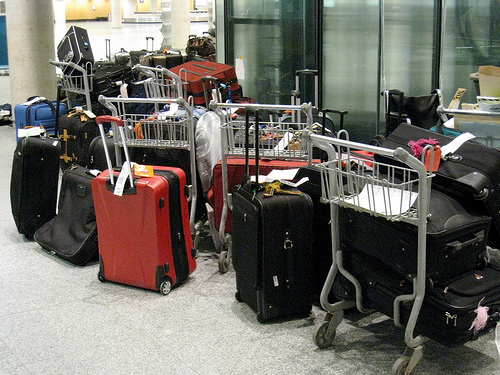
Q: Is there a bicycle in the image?
A: No, there are no bicycles.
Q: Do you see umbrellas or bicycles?
A: No, there are no bicycles or umbrellas.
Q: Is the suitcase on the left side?
A: Yes, the suitcase is on the left of the image.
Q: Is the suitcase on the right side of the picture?
A: No, the suitcase is on the left of the image.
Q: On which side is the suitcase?
A: The suitcase is on the left of the image.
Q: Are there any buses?
A: No, there are no buses.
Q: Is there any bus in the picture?
A: No, there are no buses.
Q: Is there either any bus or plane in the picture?
A: No, there are no buses or airplanes.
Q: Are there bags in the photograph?
A: Yes, there is a bag.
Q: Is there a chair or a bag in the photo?
A: Yes, there is a bag.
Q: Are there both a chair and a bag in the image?
A: No, there is a bag but no chairs.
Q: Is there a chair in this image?
A: No, there are no chairs.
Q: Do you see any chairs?
A: No, there are no chairs.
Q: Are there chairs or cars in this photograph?
A: No, there are no chairs or cars.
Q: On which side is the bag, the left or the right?
A: The bag is on the right of the image.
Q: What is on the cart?
A: The bag is on the cart.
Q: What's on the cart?
A: The bag is on the cart.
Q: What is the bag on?
A: The bag is on the cart.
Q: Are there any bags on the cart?
A: Yes, there is a bag on the cart.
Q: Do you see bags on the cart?
A: Yes, there is a bag on the cart.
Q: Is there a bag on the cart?
A: Yes, there is a bag on the cart.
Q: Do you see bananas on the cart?
A: No, there is a bag on the cart.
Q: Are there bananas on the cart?
A: No, there is a bag on the cart.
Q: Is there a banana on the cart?
A: No, there is a bag on the cart.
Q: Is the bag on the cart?
A: Yes, the bag is on the cart.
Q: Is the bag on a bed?
A: No, the bag is on the cart.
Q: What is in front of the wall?
A: The bag is in front of the wall.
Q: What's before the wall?
A: The bag is in front of the wall.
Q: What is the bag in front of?
A: The bag is in front of the wall.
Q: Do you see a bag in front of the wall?
A: Yes, there is a bag in front of the wall.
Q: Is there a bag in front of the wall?
A: Yes, there is a bag in front of the wall.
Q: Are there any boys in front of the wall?
A: No, there is a bag in front of the wall.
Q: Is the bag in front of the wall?
A: Yes, the bag is in front of the wall.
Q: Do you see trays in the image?
A: No, there are no trays.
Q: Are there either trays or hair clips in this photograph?
A: No, there are no trays or hair clips.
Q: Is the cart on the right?
A: Yes, the cart is on the right of the image.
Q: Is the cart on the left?
A: No, the cart is on the right of the image.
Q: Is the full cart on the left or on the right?
A: The cart is on the right of the image.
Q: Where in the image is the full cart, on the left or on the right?
A: The cart is on the right of the image.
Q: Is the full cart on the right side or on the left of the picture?
A: The cart is on the right of the image.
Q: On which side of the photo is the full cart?
A: The cart is on the right of the image.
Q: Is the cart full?
A: Yes, the cart is full.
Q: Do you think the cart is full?
A: Yes, the cart is full.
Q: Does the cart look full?
A: Yes, the cart is full.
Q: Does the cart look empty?
A: No, the cart is full.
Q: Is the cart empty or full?
A: The cart is full.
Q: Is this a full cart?
A: Yes, this is a full cart.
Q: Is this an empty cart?
A: No, this is a full cart.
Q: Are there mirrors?
A: No, there are no mirrors.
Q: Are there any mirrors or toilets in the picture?
A: No, there are no mirrors or toilets.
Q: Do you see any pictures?
A: No, there are no pictures.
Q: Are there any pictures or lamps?
A: No, there are no pictures or lamps.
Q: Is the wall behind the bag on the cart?
A: Yes, the wall is behind the bag.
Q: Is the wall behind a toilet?
A: No, the wall is behind the bag.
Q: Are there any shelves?
A: No, there are no shelves.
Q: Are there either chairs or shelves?
A: No, there are no shelves or chairs.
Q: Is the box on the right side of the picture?
A: Yes, the box is on the right of the image.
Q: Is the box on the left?
A: No, the box is on the right of the image.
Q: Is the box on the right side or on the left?
A: The box is on the right of the image.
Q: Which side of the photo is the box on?
A: The box is on the right of the image.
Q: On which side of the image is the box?
A: The box is on the right of the image.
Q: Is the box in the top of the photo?
A: Yes, the box is in the top of the image.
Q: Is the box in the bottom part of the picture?
A: No, the box is in the top of the image.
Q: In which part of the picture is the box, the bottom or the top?
A: The box is in the top of the image.